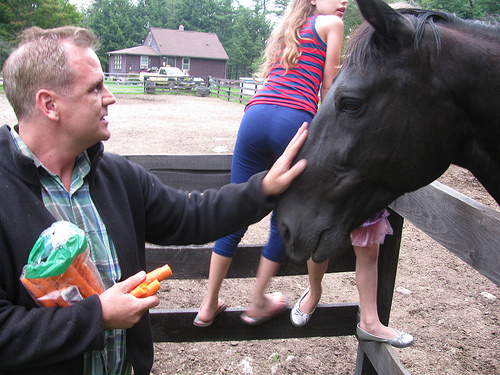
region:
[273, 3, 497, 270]
A black horse's head.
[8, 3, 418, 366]
A man petting a horse.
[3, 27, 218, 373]
A man holding a bag of carrots.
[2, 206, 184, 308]
A bag of carrots with a green top.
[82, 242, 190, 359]
Carrots in man's right hand.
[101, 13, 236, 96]
A brown house in the background.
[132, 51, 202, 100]
A pickup truck in front of house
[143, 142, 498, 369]
A wooden fence enclosure.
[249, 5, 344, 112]
Young girl with long blonde hair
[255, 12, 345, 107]
A red and blue tank top.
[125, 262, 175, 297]
the carrots in the man's hand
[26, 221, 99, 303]
the bag of carrots the man is holding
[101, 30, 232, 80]
the house behind the fence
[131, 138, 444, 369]
the wooden fence the girls are standing on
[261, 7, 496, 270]
the black horse standing by the fence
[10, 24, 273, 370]
the man touching the horse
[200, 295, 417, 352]
the shoes the girls are wearing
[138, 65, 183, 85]
the truck by the fence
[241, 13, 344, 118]
the tank top the girl is wearing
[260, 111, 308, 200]
the hand on the horse's face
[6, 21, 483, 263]
Man appreciating black horse.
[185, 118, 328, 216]
Gentle hand strokes horse.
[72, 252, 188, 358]
Carrots hand ready to feed.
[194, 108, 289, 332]
Blue pants flip-flop feet.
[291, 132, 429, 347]
Girl hidden behind horse.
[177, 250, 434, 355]
Four feet balance wood fence.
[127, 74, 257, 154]
Coral bordered wooden fence.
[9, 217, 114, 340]
Whole bag carrots if necessary.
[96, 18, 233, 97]
Brown house yellow truck.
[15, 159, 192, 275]
Black jacket blue plaid shirt.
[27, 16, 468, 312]
man petting black horse on muzzle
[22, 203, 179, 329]
man holding carrots for the horse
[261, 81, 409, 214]
man is petting the black horse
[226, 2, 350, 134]
girl is standing on wooden rails of fence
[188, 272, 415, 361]
two girls are standing on the fence rails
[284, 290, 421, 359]
one girl has silver shoes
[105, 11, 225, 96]
small red house is in the background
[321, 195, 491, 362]
the grey rails are wooden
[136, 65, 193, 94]
yellow truck parked in front of house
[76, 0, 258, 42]
green trees in the distance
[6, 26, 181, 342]
the man is holding carrots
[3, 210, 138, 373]
a bag of carrots are on his arm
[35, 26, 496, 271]
the man has his hand on a horse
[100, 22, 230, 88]
a house is in the background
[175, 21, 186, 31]
the house has a chimney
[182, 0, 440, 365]
the girls are climbing a fence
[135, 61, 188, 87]
a yellow pick up is next to a fence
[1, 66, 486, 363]
wooden fences surround the pens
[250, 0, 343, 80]
the girl has long brown hair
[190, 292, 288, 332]
the girl is wearing flip flops